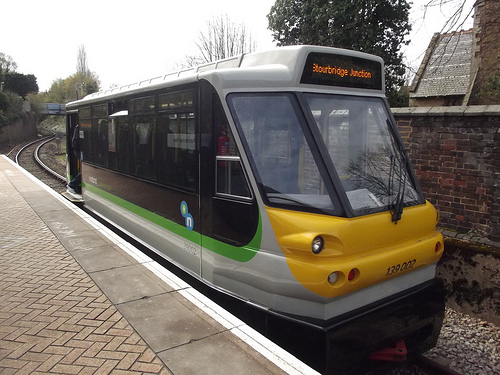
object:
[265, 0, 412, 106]
tree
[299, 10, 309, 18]
leaves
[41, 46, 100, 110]
fall trees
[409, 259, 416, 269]
numbers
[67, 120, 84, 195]
person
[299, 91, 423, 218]
windshield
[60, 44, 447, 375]
train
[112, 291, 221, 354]
streettile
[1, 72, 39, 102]
trees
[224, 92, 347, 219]
windshield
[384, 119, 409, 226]
windshield wipers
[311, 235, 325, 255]
head light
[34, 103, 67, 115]
bridge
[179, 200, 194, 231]
sign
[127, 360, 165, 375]
brick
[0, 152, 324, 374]
platform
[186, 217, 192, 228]
letters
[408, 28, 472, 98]
roof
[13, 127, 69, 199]
railroad track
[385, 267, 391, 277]
number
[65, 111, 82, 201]
door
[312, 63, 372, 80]
sign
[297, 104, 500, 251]
brick wall